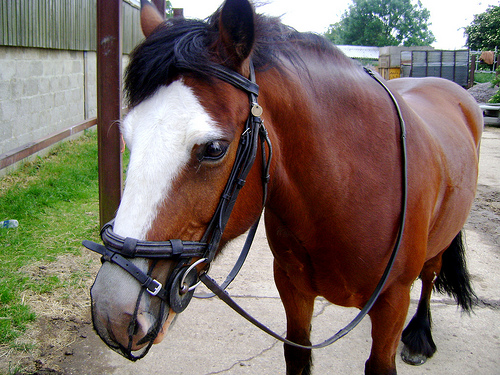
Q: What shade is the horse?
A: Brown, white, and black.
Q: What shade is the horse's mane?
A: Black.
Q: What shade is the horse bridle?
A: Black.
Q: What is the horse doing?
A: Standing.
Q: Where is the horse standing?
A: On the pavement.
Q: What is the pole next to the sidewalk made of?
A: Metal.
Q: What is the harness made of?
A: Leather.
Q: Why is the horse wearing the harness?
A: To control what direction the horse walks.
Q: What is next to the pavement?
A: Grass.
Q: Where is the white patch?
A: On the horse's face.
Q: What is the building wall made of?
A: Cement.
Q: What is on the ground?
A: Patches of green grass.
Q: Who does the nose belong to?
A: To the horse.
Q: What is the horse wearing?
A: A harness.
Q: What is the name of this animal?
A: Horse.